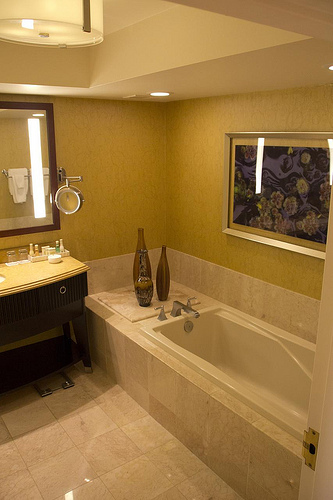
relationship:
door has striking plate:
[295, 184, 331, 494] [299, 425, 318, 473]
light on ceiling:
[150, 91, 169, 97] [1, 1, 331, 98]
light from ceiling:
[0, 0, 103, 48] [1, 1, 331, 98]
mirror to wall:
[59, 192, 78, 212] [106, 119, 168, 200]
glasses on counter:
[5, 247, 29, 263] [1, 248, 90, 294]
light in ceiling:
[150, 91, 169, 97] [1, 1, 331, 98]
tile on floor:
[27, 446, 97, 497] [1, 360, 244, 497]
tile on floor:
[56, 404, 117, 446] [1, 360, 244, 497]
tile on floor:
[76, 426, 144, 475] [1, 360, 244, 497]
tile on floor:
[146, 437, 207, 484] [1, 360, 244, 497]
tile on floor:
[99, 391, 149, 427] [1, 360, 244, 497]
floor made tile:
[1, 360, 244, 497] [44, 381, 97, 420]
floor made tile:
[1, 360, 244, 497] [2, 392, 54, 439]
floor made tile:
[1, 360, 244, 497] [99, 454, 171, 498]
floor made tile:
[1, 360, 244, 497] [27, 446, 97, 497]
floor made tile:
[1, 360, 244, 497] [78, 427, 140, 476]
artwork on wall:
[233, 144, 332, 244] [0, 81, 331, 339]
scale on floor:
[31, 367, 75, 397] [1, 360, 244, 497]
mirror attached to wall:
[51, 167, 83, 215] [0, 93, 167, 260]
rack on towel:
[2, 168, 31, 178] [8, 167, 28, 203]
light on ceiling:
[148, 85, 174, 106] [117, 47, 242, 149]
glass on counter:
[5, 248, 18, 267] [1, 248, 90, 294]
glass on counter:
[18, 248, 28, 260] [0, 240, 87, 303]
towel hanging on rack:
[8, 167, 28, 203] [2, 164, 32, 173]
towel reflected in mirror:
[8, 167, 28, 203] [0, 96, 63, 238]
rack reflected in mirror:
[2, 164, 32, 173] [0, 96, 63, 238]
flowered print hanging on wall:
[231, 142, 329, 244] [163, 84, 325, 302]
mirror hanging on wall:
[0, 96, 63, 238] [0, 93, 167, 260]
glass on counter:
[7, 251, 18, 263] [0, 255, 90, 296]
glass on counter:
[18, 247, 28, 262] [0, 255, 90, 296]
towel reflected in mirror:
[8, 167, 28, 203] [2, 102, 60, 237]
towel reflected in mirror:
[8, 167, 28, 195] [0, 109, 53, 230]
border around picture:
[228, 137, 329, 250] [232, 144, 330, 243]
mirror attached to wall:
[0, 109, 54, 232] [0, 93, 167, 260]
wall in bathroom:
[99, 112, 209, 210] [0, 0, 332, 498]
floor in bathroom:
[1, 421, 168, 497] [0, 0, 332, 498]